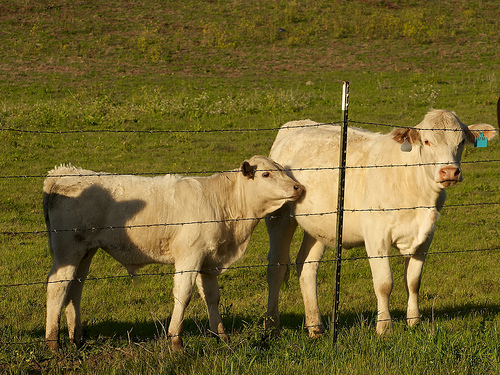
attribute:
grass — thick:
[80, 50, 214, 133]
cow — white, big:
[265, 106, 496, 338]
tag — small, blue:
[467, 125, 490, 160]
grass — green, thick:
[29, 95, 132, 125]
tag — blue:
[475, 132, 487, 149]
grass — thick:
[172, 309, 497, 373]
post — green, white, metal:
[324, 76, 353, 348]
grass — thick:
[0, 0, 499, 374]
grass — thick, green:
[204, 300, 356, 371]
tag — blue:
[465, 121, 497, 150]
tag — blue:
[463, 127, 498, 163]